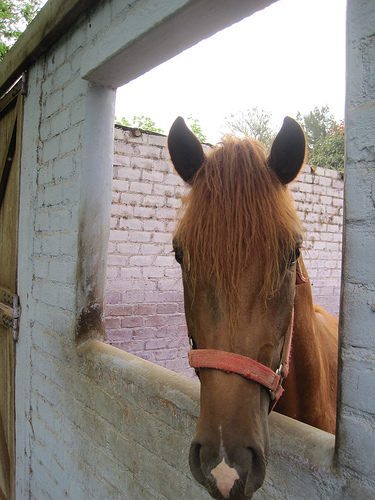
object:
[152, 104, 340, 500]
horse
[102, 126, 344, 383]
wall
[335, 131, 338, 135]
flowers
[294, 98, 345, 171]
bushes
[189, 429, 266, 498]
nose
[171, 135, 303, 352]
hair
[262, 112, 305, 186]
left ear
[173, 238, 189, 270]
right eye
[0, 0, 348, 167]
sky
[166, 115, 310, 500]
head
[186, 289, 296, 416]
bridle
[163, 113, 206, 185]
ears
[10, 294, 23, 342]
hinge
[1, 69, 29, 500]
door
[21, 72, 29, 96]
hinge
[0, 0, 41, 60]
trees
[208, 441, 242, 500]
spot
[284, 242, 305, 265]
left eye